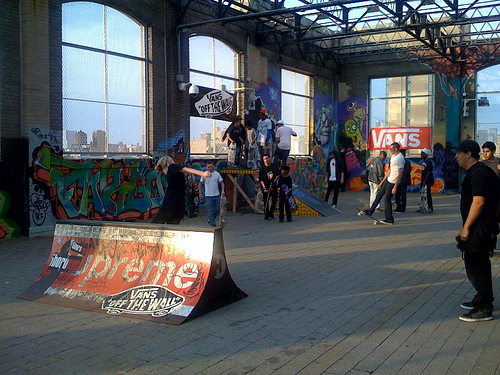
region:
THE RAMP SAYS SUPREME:
[17, 213, 248, 338]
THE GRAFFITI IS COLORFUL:
[30, 140, 166, 223]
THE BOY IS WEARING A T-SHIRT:
[155, 162, 197, 222]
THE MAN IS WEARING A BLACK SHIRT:
[451, 157, 497, 237]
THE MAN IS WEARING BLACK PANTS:
[455, 222, 498, 309]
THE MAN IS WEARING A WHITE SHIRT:
[380, 150, 407, 186]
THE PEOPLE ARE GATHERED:
[150, 110, 497, 327]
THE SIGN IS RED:
[365, 122, 437, 153]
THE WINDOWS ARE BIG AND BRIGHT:
[56, 0, 497, 171]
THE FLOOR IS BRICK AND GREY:
[0, 185, 495, 374]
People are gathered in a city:
[21, 38, 491, 353]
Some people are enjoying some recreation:
[11, 32, 496, 347]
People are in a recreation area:
[6, 20, 491, 358]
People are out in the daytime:
[13, 28, 489, 344]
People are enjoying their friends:
[6, 20, 496, 361]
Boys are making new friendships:
[0, 23, 495, 373]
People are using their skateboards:
[11, 22, 496, 367]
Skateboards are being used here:
[1, 40, 493, 350]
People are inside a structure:
[31, 5, 481, 346]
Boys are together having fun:
[3, 8, 495, 354]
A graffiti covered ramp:
[17, 215, 253, 325]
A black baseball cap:
[446, 131, 488, 156]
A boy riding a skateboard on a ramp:
[140, 141, 211, 231]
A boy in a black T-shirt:
[135, 145, 215, 225]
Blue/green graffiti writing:
[31, 135, 176, 225]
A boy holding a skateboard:
[192, 156, 232, 227]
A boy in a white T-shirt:
[191, 155, 232, 225]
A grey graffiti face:
[310, 95, 335, 141]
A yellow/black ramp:
[255, 160, 341, 226]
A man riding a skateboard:
[353, 132, 409, 229]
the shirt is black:
[449, 168, 493, 267]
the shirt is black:
[147, 162, 182, 214]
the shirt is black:
[159, 165, 201, 227]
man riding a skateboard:
[344, 127, 419, 299]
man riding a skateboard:
[132, 147, 214, 257]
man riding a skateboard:
[364, 115, 429, 262]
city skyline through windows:
[64, 127, 310, 155]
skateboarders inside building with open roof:
[2, 2, 497, 374]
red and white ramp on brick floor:
[1, 192, 498, 371]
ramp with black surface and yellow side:
[265, 182, 345, 219]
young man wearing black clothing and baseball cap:
[453, 134, 498, 322]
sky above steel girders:
[226, 0, 498, 42]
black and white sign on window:
[185, 33, 242, 158]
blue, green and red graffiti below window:
[50, 0, 160, 222]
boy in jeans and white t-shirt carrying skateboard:
[197, 162, 230, 227]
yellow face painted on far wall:
[343, 117, 365, 149]